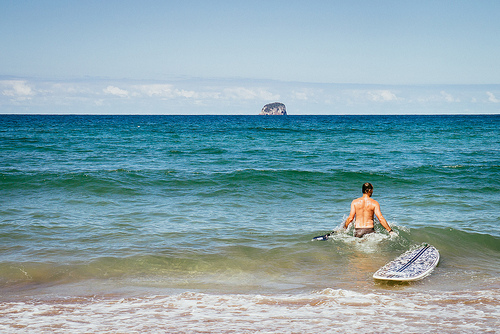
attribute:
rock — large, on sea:
[246, 86, 302, 119]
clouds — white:
[21, 60, 465, 113]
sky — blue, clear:
[20, 8, 492, 107]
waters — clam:
[44, 130, 457, 166]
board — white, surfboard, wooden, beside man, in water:
[355, 242, 439, 303]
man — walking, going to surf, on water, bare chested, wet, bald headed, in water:
[328, 174, 394, 250]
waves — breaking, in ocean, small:
[55, 124, 236, 185]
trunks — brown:
[347, 220, 377, 238]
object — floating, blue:
[307, 229, 330, 249]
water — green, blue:
[186, 133, 407, 264]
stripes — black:
[392, 232, 438, 280]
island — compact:
[15, 102, 472, 325]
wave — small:
[32, 133, 318, 204]